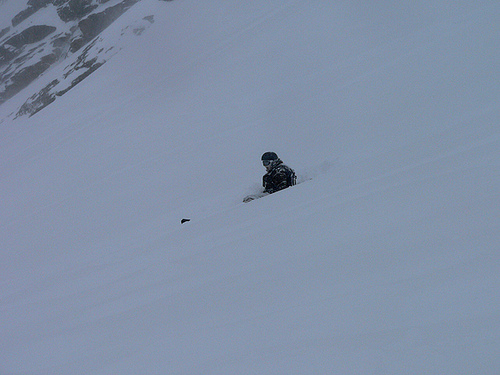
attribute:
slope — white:
[78, 41, 391, 361]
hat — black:
[244, 143, 291, 179]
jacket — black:
[264, 165, 294, 189]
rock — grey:
[22, 100, 47, 110]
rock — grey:
[7, 64, 34, 93]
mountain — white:
[107, 64, 430, 272]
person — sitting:
[230, 140, 335, 222]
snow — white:
[124, 43, 460, 348]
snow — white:
[87, 219, 418, 362]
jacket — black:
[218, 144, 307, 188]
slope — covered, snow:
[55, 47, 498, 370]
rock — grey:
[23, 33, 109, 105]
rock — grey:
[14, 21, 91, 81]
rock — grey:
[38, 27, 109, 97]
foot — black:
[164, 200, 206, 238]